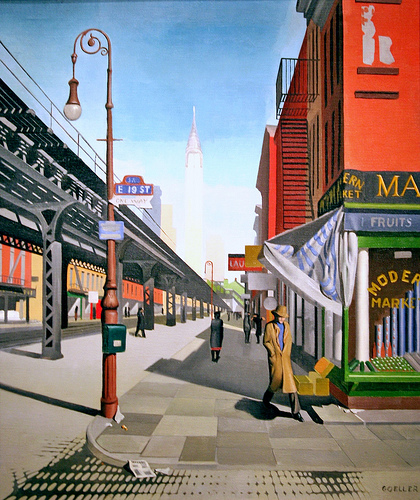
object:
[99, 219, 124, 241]
sign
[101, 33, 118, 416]
post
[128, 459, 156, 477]
newspaper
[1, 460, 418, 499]
street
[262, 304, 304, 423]
man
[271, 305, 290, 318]
hat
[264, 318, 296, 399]
coat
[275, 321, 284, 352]
shirt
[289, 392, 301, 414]
pants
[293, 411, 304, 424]
shoe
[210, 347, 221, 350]
dress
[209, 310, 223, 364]
woman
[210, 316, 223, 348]
coat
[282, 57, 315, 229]
fire escape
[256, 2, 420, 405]
building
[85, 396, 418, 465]
sidewalk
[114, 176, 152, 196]
street sign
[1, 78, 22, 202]
traintracks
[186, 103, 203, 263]
empire building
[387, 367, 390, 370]
fruit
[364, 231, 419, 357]
window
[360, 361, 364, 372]
zuchini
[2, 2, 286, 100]
sky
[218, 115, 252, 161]
clouds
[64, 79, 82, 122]
light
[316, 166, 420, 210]
sign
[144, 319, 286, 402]
shadow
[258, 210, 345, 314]
canopy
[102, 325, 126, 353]
mailbox